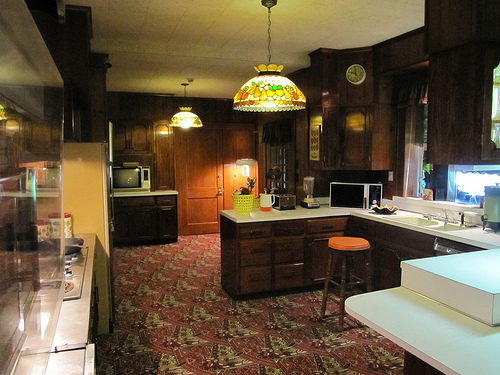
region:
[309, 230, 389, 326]
a stool in front of a sink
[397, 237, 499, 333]
a large white box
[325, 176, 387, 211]
a microwave on a counter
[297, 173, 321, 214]
a blender on a counter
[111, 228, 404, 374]
a red carpet in a kitchen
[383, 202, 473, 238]
a sink in front of a window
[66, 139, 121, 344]
a yellow refrigerator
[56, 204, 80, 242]
a cannister next to a refrigerator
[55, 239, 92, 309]
an electric stove top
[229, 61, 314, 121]
a ceiling light hanging down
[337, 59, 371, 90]
white clock on wall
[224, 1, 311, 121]
lamp hangs from ceiling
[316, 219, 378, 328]
an orange stool on kitchen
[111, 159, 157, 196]
a TV on a kitchen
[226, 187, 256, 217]
a yellow basket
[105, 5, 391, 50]
ceiling is white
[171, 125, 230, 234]
door of a kitchen is brown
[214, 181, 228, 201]
handle of door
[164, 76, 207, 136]
a lamp hang from ceiling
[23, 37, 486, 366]
A kitchen scene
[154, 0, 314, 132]
Light fixtures are hanging from the ceiling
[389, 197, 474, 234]
The kitchen sink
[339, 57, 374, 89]
A clock is on the wall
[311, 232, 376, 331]
A stool is sitting here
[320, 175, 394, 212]
This is a microwave oven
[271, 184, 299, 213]
A toaster is on the counter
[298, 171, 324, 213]
This is a blender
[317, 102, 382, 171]
Kitchen cabinets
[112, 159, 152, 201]
The television is turned off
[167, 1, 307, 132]
colorful lights hanging from the ceiling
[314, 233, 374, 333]
brown and orange stool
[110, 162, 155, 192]
old, white and gray television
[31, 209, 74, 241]
white and red food containers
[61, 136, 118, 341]
yellow and white refridgerator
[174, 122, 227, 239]
brown wood door in the middle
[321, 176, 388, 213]
black and white microwave on the counter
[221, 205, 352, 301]
brown cabinets and white countertop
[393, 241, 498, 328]
white box on the countertop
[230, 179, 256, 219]
yellow plastic storage container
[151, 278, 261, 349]
the kitchen is carpeted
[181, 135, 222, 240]
the doors are wooden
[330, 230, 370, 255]
the top of the stool is orange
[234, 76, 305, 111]
the light is decorated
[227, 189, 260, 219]
the basket is yellow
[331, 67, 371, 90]
a clock is on the wall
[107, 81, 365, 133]
the ceiling has two lights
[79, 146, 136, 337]
the fridge is closed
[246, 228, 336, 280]
the drawers are closed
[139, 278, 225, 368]
the carpet has diagrams